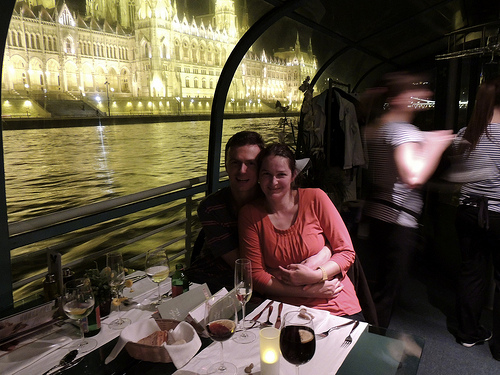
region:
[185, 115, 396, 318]
two people having dinner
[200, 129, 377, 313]
two people eating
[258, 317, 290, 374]
the candle on the table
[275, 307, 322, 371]
the glass of wine on the table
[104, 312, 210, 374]
the basket of bread on the table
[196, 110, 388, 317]
the man is holding the woman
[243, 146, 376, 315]
the woman is sitting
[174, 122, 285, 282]
the man is sitting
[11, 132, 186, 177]
the water is calm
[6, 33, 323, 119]
the building is lit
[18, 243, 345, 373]
Table set for dinner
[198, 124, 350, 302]
Young couple hugging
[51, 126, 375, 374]
Young couple having dinner together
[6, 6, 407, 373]
Young couple on dinner cruise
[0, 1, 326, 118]
Historic building lit at night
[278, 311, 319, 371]
Full wine glass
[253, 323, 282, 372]
Lit white candle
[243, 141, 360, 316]
Young woman wearing salmon colored shirt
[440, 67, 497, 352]
Woman wearing stripped shirt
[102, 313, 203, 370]
Empty bread basket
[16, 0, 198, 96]
A Brightly Lit Building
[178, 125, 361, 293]
A Man and a woman in focus in the photo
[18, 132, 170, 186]
A body of water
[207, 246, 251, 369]
Two fine drinking glasses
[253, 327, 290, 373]
A nice lit Candle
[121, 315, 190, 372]
A Bread Basket on the table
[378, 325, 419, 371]
A Bluish Green Table top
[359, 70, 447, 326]
A Blurry photo of a lady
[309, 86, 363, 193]
Some Jackets hanging to the side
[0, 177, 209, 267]
Some safety railing on to protect people from falling in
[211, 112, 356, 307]
a couple posing at a restuarant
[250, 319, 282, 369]
a white candle on the table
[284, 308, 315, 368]
a glass of red wine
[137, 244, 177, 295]
a glass of white wine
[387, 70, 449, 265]
a woman standing behind the couple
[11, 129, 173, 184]
a calm river outside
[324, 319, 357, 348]
silverware on the table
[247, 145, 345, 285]
a woman wearing a pink top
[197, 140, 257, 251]
a man wearing a stripe shirt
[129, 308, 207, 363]
a basket bread on the table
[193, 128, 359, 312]
a man and woman hugging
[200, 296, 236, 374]
a glass of red wine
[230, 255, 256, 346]
a glass of red wine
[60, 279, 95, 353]
a glass of white wine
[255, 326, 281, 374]
a frosted votive candle holder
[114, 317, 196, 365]
a wicker basket of bread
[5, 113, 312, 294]
a body of water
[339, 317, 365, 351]
a silver fork utensil